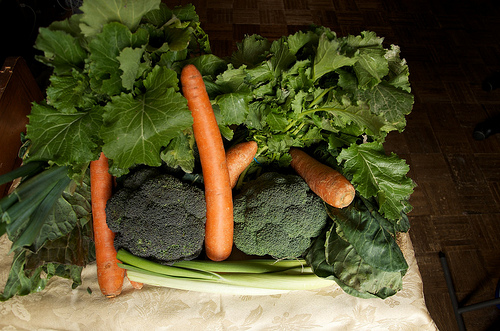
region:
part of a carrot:
[214, 235, 226, 252]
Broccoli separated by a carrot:
[106, 168, 323, 265]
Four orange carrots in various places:
[83, 65, 354, 297]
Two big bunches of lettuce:
[23, 3, 409, 202]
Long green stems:
[114, 240, 359, 301]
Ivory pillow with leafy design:
[1, 230, 429, 329]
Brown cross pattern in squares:
[412, 43, 497, 293]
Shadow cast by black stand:
[461, 259, 496, 326]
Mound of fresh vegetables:
[12, 3, 402, 288]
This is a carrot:
[72, 111, 149, 318]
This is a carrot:
[175, 51, 240, 273]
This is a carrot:
[273, 127, 363, 221]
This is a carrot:
[274, 130, 379, 232]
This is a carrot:
[76, 127, 136, 307]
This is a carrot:
[285, 127, 362, 227]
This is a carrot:
[180, 57, 237, 282]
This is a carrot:
[218, 116, 265, 205]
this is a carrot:
[77, 141, 127, 283]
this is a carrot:
[170, 54, 241, 276]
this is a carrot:
[217, 130, 269, 193]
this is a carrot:
[281, 118, 359, 225]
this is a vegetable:
[44, 30, 118, 134]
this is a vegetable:
[312, 202, 407, 298]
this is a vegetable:
[332, 135, 422, 230]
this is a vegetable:
[15, 145, 85, 272]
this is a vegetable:
[246, 59, 342, 155]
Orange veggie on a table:
[176, 53, 233, 264]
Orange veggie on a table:
[224, 136, 264, 186]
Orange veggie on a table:
[276, 143, 378, 198]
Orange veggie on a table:
[71, 147, 133, 326]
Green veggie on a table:
[228, 183, 330, 257]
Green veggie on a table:
[107, 170, 210, 250]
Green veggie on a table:
[115, 250, 332, 287]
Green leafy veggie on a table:
[319, 29, 415, 204]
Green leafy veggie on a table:
[243, 33, 305, 156]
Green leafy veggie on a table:
[21, 19, 240, 179]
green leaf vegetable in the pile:
[340, 131, 421, 216]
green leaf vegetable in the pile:
[315, 52, 415, 132]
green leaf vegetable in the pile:
[200, 47, 246, 93]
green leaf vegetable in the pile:
[221, 90, 256, 127]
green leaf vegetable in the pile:
[310, 26, 350, 84]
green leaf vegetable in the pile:
[115, 31, 140, 87]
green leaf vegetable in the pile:
[95, 85, 185, 176]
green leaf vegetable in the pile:
[18, 95, 103, 171]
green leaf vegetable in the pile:
[0, 158, 80, 246]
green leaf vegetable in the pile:
[85, 18, 151, 61]